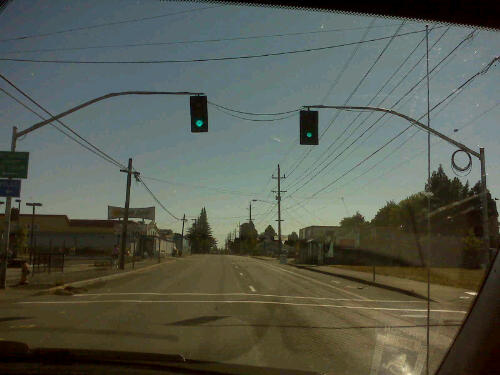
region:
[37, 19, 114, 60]
white clouds in blue sky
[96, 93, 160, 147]
white clouds in blue sky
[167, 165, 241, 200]
white clouds in blue sky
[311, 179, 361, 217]
white clouds in blue sky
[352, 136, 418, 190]
white clouds in blue sky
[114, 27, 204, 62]
white clouds in blue sky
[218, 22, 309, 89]
white clouds in blue sky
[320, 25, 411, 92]
white clouds in blue sky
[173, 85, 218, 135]
green traffic light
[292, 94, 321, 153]
green traffic light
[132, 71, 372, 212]
two green stop lights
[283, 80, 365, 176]
a green stop light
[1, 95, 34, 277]
street signs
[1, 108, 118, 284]
street signs on a metal pole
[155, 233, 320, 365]
white lines on a tard road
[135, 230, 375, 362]
a tard road with white lines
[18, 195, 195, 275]
a yellow building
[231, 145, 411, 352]
power lines on the side of a road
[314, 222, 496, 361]
a sidewalk along side a road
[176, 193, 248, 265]
tall green trees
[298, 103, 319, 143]
Stoplight on green.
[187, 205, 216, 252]
A green tree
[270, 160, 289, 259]
A powerline pole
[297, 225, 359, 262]
A building on a street.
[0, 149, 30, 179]
A street sign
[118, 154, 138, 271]
A pole on the side of a street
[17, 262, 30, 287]
A red fire hydrant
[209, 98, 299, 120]
A powerline connecting stop lights.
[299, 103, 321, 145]
Stoplight that has turned green.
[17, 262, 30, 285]
Fire hydrant present on a sidewalk.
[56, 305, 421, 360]
The street is made of asphalt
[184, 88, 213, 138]
The stop light is the color green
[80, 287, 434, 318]
The lines in the middle of the street are white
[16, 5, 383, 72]
The electrical wires above the street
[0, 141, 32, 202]
The signs on the end on the street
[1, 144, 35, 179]
The street sign is green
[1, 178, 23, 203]
The street sign is blue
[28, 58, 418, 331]
The window of a vehicle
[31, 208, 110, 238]
The top of the building is red and yellow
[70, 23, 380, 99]
The sky is clear and blue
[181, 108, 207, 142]
green signal light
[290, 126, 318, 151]
green signal light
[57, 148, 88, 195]
white clouds in blue sky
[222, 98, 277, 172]
white clouds in blue sky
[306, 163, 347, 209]
white clouds in blue sky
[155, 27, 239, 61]
white clouds in blue sky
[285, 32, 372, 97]
white clouds in blue sky